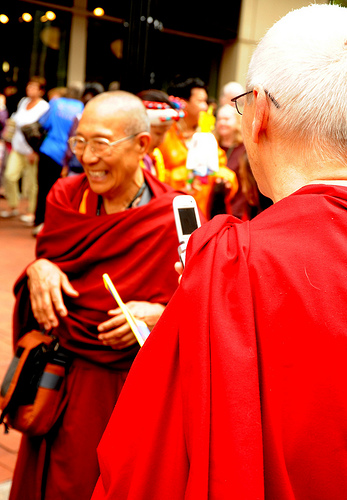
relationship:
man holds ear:
[76, 3, 345, 498] [240, 89, 297, 139]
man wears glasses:
[43, 112, 181, 452] [65, 131, 136, 153]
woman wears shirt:
[3, 75, 43, 211] [11, 99, 43, 154]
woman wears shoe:
[3, 75, 43, 211] [0, 206, 15, 220]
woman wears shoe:
[3, 75, 43, 211] [18, 212, 35, 226]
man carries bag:
[43, 112, 181, 452] [3, 333, 70, 432]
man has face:
[43, 112, 181, 452] [66, 105, 118, 195]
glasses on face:
[65, 131, 136, 153] [66, 105, 118, 195]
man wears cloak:
[76, 3, 345, 498] [91, 189, 344, 499]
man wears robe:
[43, 112, 181, 452] [14, 170, 172, 499]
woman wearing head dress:
[133, 87, 190, 182] [138, 93, 186, 129]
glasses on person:
[65, 131, 136, 153] [12, 80, 189, 498]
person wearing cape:
[12, 80, 189, 498] [5, 154, 191, 489]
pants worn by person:
[3, 149, 37, 212] [2, 79, 46, 219]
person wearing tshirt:
[2, 79, 46, 219] [10, 97, 49, 153]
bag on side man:
[3, 320, 79, 435] [11, 72, 200, 371]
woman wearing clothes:
[162, 73, 245, 215] [177, 131, 260, 217]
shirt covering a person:
[39, 98, 87, 164] [28, 70, 197, 496]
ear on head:
[240, 89, 297, 139] [236, 3, 345, 194]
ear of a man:
[240, 89, 297, 139] [76, 3, 345, 498]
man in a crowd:
[43, 112, 172, 197] [0, 6, 345, 491]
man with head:
[43, 112, 181, 452] [66, 89, 151, 193]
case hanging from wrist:
[0, 327, 74, 439] [25, 257, 48, 272]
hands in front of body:
[16, 259, 170, 361] [0, 89, 207, 498]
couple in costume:
[142, 73, 234, 234] [159, 125, 234, 216]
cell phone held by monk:
[173, 194, 201, 263] [87, 3, 340, 498]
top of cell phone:
[171, 193, 201, 239] [173, 194, 201, 263]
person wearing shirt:
[30, 81, 84, 239] [36, 96, 82, 166]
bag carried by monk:
[3, 320, 79, 435] [4, 88, 177, 498]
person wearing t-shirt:
[0, 67, 66, 228] [9, 96, 51, 155]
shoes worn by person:
[1, 209, 37, 223] [2, 79, 46, 219]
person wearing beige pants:
[2, 79, 46, 219] [5, 148, 37, 211]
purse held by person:
[22, 122, 48, 149] [30, 81, 84, 239]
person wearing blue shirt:
[30, 81, 84, 239] [38, 96, 86, 164]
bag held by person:
[1, 120, 16, 143] [2, 79, 46, 219]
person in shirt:
[2, 79, 46, 219] [8, 95, 49, 153]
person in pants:
[2, 79, 46, 219] [2, 148, 39, 211]